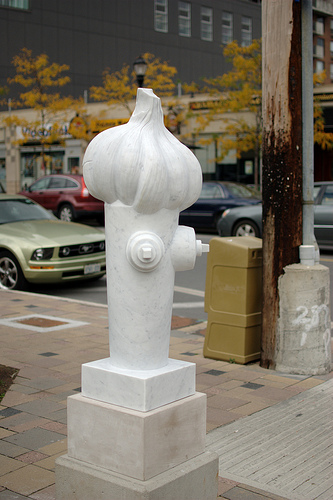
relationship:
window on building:
[177, 0, 190, 37] [0, 0, 332, 112]